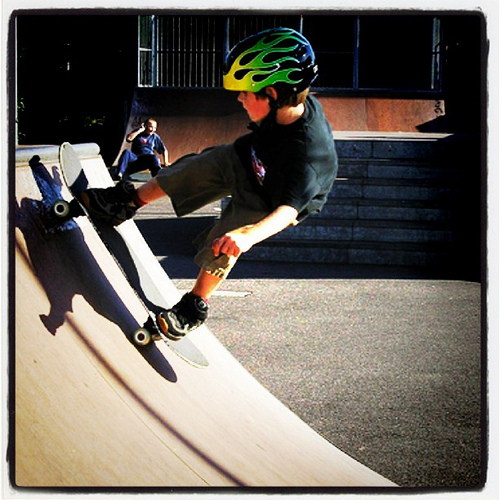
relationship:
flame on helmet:
[235, 37, 292, 94] [217, 30, 330, 93]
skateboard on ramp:
[64, 149, 196, 350] [28, 115, 417, 495]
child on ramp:
[111, 80, 361, 321] [28, 115, 417, 495]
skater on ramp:
[129, 112, 179, 175] [131, 92, 464, 210]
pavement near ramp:
[228, 281, 497, 443] [28, 115, 417, 495]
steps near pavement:
[267, 162, 486, 272] [228, 281, 497, 443]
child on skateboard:
[111, 80, 361, 321] [64, 149, 196, 350]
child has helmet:
[111, 80, 361, 321] [217, 30, 330, 93]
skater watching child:
[129, 112, 179, 175] [111, 80, 361, 321]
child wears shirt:
[111, 80, 361, 321] [250, 110, 345, 211]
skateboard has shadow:
[64, 149, 196, 350] [23, 181, 169, 385]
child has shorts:
[111, 80, 361, 321] [159, 121, 262, 262]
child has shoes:
[111, 80, 361, 321] [64, 180, 199, 346]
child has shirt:
[111, 80, 361, 321] [250, 110, 345, 211]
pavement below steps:
[228, 281, 497, 443] [267, 162, 486, 272]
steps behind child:
[267, 162, 486, 272] [111, 80, 361, 321]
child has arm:
[111, 80, 361, 321] [224, 202, 289, 249]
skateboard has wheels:
[64, 149, 196, 350] [123, 319, 146, 358]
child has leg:
[111, 80, 361, 321] [139, 175, 185, 205]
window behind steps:
[354, 19, 428, 95] [267, 162, 486, 272]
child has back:
[111, 80, 361, 321] [297, 90, 334, 213]